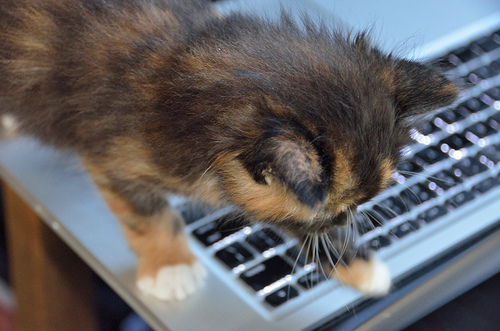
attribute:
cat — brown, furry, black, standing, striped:
[0, 0, 456, 303]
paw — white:
[128, 259, 208, 301]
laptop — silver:
[2, 0, 498, 327]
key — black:
[215, 239, 255, 274]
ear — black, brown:
[389, 54, 462, 128]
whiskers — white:
[282, 231, 352, 299]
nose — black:
[332, 210, 358, 227]